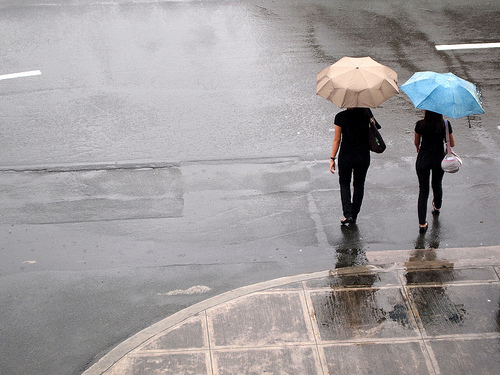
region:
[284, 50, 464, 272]
two people hold umbrellas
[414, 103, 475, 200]
woman holds grey bag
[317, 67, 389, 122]
woman holds tan umbrella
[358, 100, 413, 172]
woman holds black bag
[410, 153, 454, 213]
woman has black pants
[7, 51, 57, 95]
white lines on wet road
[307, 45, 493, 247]
two people holding umbrella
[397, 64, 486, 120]
umbrella is color blue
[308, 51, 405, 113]
umbrella is color brown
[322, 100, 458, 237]
two people wearing black cloths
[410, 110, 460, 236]
person wearing a purse on right shoulder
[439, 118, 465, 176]
a purple purse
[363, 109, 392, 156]
a black purse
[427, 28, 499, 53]
a white line on road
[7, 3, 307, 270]
the road is wet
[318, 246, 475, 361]
reflection of people on wet road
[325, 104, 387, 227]
PERSON WALKING IN THE RAIN CARRYING A BROWN UMBRELLA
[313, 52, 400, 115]
BROWN UMBRELLA OVER TOP OF PERSON WITH BLACK PURSE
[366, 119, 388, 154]
BLACK PURSE THE WOMAN WITH BROWN UMBRELLA IS CARRYING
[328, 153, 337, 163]
WATCH ON THE PERSON CARRYING BROWN UMBRELLA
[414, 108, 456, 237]
PERSON CARRYING BLUE UMBRELLA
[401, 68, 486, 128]
BLUE UMBRELLA THE PERSON WITH THE WHITE PURSE IS CARRYING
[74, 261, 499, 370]
SIDEWALK WET FROM A RAINY DAY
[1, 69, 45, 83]
WHITE PARKING LINE IN A PARKING LOT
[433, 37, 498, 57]
WHITE PARKING LINE IN A PARKING LOT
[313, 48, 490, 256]
Two pedestrians holding umbrellas in an urban rainy environment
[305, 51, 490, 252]
Two pedestrians holding umbrellas in an urban rainy environment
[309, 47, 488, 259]
Two pedestrians holding umbrellas in an urban rainy environment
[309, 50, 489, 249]
Two pedestrians holding umbrellas in an urban rainy environment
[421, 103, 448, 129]
the head of a woman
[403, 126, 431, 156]
the arm of a woman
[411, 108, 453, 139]
the hair of a woman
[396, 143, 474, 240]
the legs of a woman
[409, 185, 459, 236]
the feet of a woman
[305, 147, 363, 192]
the hand of a woman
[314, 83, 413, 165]
a woman wearing a shirt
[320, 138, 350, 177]
the wrist of a woman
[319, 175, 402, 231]
a woman wearing shoes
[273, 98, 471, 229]
two girls on the street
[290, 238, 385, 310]
reflection on the ground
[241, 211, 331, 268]
wet ground under the girls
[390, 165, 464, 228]
legs on the girl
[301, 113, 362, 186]
arm of the girl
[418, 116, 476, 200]
bag on side of girl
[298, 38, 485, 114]
blue and brown umbrella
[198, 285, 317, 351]
a dirty and stained pavement portion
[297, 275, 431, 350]
a dirty and stained pavement portion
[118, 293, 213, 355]
a dirty and stained pavement portion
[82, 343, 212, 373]
a dirty and stained pavement portion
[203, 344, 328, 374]
a dirty and stained pavement portion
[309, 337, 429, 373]
a dirty and stained pavement portion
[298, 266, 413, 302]
a dirty and stained pavement portion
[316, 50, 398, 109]
the umbrella is spread open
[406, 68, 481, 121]
the umbrella is spread open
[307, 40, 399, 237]
the woman is holding and umbrella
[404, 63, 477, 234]
the woman is holding and umbrella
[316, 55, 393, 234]
the woman is taking a step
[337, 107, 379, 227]
the woman is wearing a black oufit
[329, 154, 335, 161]
the woman is wearing a wrist watch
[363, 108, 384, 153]
the woman is carrying a purse